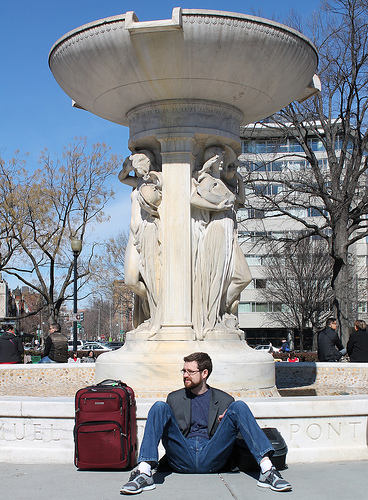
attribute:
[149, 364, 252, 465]
man — sitting, waiting, happy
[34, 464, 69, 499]
ground — clean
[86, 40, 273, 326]
statue — old, silver, large, stone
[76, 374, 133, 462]
luggage — red, black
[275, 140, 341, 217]
tree — bare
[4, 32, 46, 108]
sky — blue